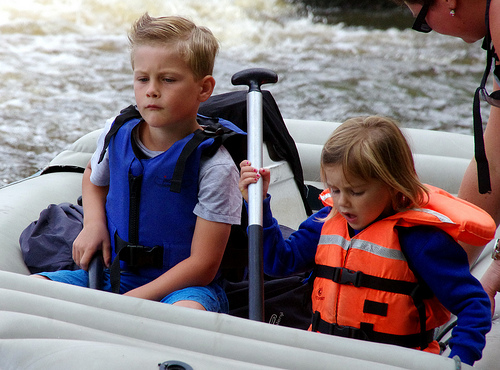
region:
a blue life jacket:
[110, 128, 200, 283]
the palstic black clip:
[332, 264, 362, 291]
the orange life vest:
[306, 225, 426, 351]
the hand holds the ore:
[236, 152, 271, 202]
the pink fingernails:
[245, 157, 268, 189]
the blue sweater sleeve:
[397, 227, 497, 364]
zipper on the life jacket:
[124, 171, 146, 252]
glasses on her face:
[396, 0, 441, 38]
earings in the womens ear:
[448, 6, 455, 20]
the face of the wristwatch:
[487, 237, 499, 264]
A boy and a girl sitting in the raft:
[86, 2, 472, 342]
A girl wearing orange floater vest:
[285, 95, 481, 352]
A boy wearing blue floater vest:
[85, 101, 241, 315]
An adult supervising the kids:
[403, 0, 498, 332]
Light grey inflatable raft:
[20, 288, 217, 368]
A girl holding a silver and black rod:
[228, 61, 475, 338]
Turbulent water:
[12, 22, 101, 137]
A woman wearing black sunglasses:
[396, 1, 477, 46]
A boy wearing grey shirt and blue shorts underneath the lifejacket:
[73, 10, 234, 301]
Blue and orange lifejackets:
[86, 120, 466, 330]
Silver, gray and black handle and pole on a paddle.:
[230, 63, 277, 324]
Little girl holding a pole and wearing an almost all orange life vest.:
[237, 112, 489, 368]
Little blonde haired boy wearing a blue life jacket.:
[30, 7, 245, 315]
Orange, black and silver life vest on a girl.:
[307, 191, 494, 354]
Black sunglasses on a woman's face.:
[410, 0, 440, 37]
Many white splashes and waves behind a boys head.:
[222, 0, 295, 56]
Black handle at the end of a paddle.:
[229, 68, 280, 86]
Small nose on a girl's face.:
[337, 185, 352, 210]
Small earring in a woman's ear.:
[447, 3, 456, 19]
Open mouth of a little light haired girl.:
[340, 210, 357, 220]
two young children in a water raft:
[54, 0, 438, 302]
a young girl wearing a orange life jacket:
[298, 112, 430, 317]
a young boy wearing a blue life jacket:
[68, 12, 250, 262]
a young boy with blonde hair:
[128, 17, 245, 122]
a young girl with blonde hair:
[299, 93, 431, 241]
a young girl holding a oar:
[216, 59, 443, 313]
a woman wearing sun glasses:
[391, 5, 486, 46]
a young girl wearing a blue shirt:
[276, 145, 461, 327]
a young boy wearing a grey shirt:
[93, 31, 244, 251]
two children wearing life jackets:
[7, 35, 464, 344]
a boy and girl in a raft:
[87, 6, 498, 351]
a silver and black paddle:
[234, 51, 284, 315]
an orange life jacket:
[288, 188, 420, 343]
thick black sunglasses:
[402, 1, 452, 36]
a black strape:
[457, 61, 497, 203]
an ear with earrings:
[445, 5, 462, 22]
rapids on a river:
[1, 0, 314, 42]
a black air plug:
[146, 346, 192, 368]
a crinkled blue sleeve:
[402, 226, 490, 367]